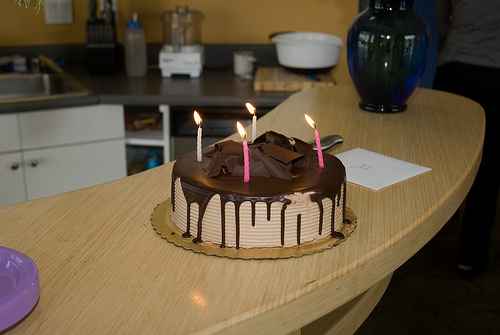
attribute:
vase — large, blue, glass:
[344, 1, 430, 113]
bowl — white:
[254, 31, 359, 91]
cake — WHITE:
[103, 93, 407, 260]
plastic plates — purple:
[0, 237, 45, 327]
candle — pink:
[240, 138, 249, 183]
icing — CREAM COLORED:
[168, 131, 348, 213]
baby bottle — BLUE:
[123, 11, 146, 76]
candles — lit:
[171, 87, 343, 154]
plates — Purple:
[1, 246, 48, 333]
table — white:
[11, 87, 492, 331]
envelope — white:
[333, 144, 435, 191]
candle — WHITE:
[251, 116, 256, 147]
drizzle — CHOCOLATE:
[169, 172, 349, 247]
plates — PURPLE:
[4, 243, 40, 333]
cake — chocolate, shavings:
[151, 65, 370, 269]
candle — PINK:
[312, 129, 325, 168]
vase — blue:
[343, 1, 435, 120]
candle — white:
[240, 103, 266, 143]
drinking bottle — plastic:
[118, 15, 155, 86]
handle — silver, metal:
[312, 129, 345, 152]